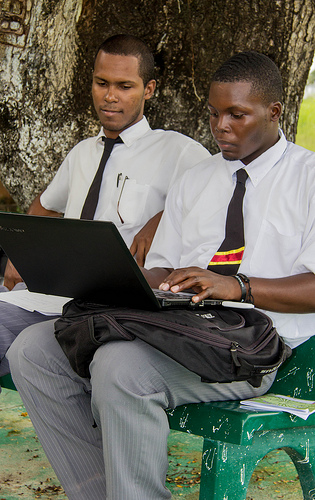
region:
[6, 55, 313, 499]
A darker skinned guy on a laptop.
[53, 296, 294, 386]
A black bookbag on a guy's lap.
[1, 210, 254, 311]
A black laptop a guy is holding.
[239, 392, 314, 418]
A white and green book lying on the end of the bench.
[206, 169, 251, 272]
A black tie with a red and gold stripes on it.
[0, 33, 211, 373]
A lighter skinned guy sitting on a bench.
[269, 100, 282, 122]
A darker colored guys left ear.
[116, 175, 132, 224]
A pair of glasses in a lightered colored guys front pocket.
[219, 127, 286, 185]
White collar around the darker skinned guys neck.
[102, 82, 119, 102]
Nose on the lighter skinned guys face.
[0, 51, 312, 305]
man typing on computer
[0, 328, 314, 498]
green bench with white spots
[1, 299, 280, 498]
gray slacks being worn by men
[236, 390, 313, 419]
booklet filled with information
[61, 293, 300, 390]
backpack used for carrying items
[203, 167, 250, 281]
tie with yellow, red, and black pattern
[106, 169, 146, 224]
glasses and pen in breast pocket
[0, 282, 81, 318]
booklet opened on lap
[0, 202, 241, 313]
computer opened on lap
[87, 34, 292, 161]
two focused males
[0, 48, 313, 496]
a man in a white shirt using a laptop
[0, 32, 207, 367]
man in white shirt next to man with laptop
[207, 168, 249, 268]
tie with red and yellow on it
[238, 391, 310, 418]
green booklet on the bench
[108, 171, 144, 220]
pocket with part of spectacles hanging out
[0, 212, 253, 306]
laptop being used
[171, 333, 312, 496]
part of the green bench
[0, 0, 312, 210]
massive tree trunk behind the men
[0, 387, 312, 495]
ground the bench is on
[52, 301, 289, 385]
bag the laptop is sitting on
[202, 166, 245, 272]
black tie with red and yellow stripes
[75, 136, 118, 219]
solid black tie worn on white shirt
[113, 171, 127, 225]
glasses in shirt pocket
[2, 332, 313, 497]
dirty green bench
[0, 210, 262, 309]
black laptop on guy's lap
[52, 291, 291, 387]
black backpack underneath a laptop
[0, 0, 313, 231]
wide brown tree trunk behind two guys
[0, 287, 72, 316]
Paper notes on guy's lap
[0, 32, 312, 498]
two guys sitting on a bench looking at laptop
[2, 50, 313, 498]
guy in white shirt typing on his laptop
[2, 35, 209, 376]
man is sitting next to man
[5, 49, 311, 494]
man is sitting next to man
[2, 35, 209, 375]
man sitting on green bench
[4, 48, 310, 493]
man sitting on green bench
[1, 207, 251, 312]
man holding black laptop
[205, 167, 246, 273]
man wearing black tie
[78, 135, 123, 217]
man wearing black tie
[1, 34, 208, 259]
man wearing white shirt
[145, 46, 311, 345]
man wearing white shirt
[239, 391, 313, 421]
book laying on green bench